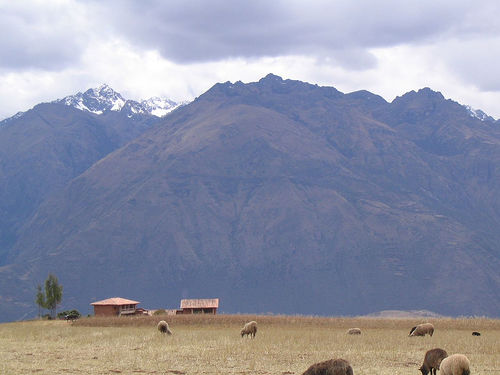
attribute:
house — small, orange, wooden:
[81, 293, 228, 323]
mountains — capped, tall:
[0, 72, 499, 318]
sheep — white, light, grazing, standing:
[153, 321, 489, 372]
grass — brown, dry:
[3, 321, 498, 372]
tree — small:
[31, 272, 81, 321]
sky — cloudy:
[0, 0, 499, 110]